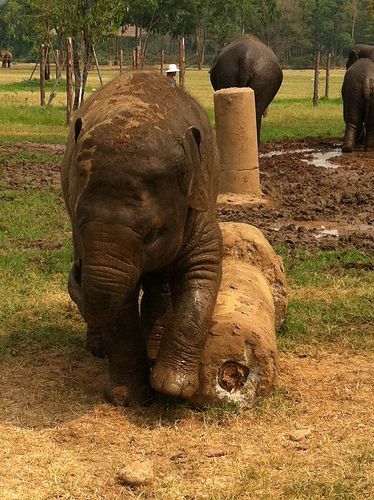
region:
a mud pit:
[271, 143, 373, 265]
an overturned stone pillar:
[182, 231, 285, 410]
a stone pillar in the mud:
[199, 73, 277, 213]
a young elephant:
[67, 59, 239, 405]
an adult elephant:
[209, 30, 301, 153]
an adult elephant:
[314, 23, 372, 155]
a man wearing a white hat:
[162, 47, 192, 90]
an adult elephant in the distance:
[0, 36, 20, 75]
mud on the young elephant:
[106, 80, 219, 413]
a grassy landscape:
[0, 59, 372, 130]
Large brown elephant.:
[75, 98, 281, 321]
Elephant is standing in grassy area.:
[62, 323, 170, 431]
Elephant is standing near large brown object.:
[132, 277, 301, 434]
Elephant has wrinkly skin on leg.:
[83, 244, 124, 349]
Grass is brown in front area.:
[156, 427, 333, 470]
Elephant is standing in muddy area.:
[320, 127, 366, 178]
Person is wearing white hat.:
[159, 49, 183, 78]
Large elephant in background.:
[2, 43, 22, 66]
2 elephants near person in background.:
[203, 34, 370, 92]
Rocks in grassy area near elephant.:
[93, 437, 139, 492]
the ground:
[240, 448, 270, 495]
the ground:
[186, 426, 223, 490]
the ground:
[231, 448, 241, 473]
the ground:
[218, 459, 242, 490]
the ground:
[230, 460, 244, 494]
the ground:
[237, 425, 262, 469]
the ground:
[222, 435, 238, 463]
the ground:
[225, 481, 234, 495]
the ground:
[236, 479, 238, 489]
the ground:
[215, 476, 231, 494]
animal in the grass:
[41, 58, 213, 338]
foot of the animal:
[148, 355, 200, 412]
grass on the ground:
[295, 303, 355, 351]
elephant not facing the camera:
[212, 31, 291, 112]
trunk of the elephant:
[71, 237, 151, 327]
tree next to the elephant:
[69, 6, 120, 50]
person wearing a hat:
[163, 57, 186, 81]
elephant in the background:
[0, 44, 22, 77]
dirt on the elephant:
[87, 62, 164, 151]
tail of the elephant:
[224, 56, 266, 100]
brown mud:
[284, 160, 354, 254]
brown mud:
[289, 136, 328, 207]